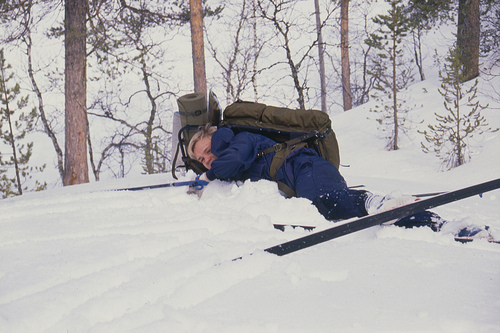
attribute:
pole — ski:
[77, 176, 209, 193]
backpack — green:
[224, 97, 346, 167]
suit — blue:
[225, 132, 362, 226]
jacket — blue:
[205, 124, 318, 195]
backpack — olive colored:
[217, 100, 338, 194]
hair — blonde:
[185, 123, 217, 158]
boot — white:
[350, 165, 443, 233]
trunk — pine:
[64, 10, 90, 182]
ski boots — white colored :
[351, 180, 418, 220]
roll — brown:
[173, 93, 211, 124]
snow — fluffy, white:
[85, 215, 215, 311]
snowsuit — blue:
[215, 127, 339, 202]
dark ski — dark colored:
[266, 177, 498, 264]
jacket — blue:
[191, 123, 342, 215]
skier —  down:
[178, 103, 495, 255]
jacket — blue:
[205, 124, 318, 186]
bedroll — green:
[176, 92, 220, 129]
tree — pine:
[2, 44, 53, 198]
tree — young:
[165, 44, 436, 121]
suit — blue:
[209, 125, 490, 243]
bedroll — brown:
[184, 92, 221, 136]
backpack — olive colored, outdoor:
[222, 100, 339, 167]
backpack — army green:
[168, 92, 340, 179]